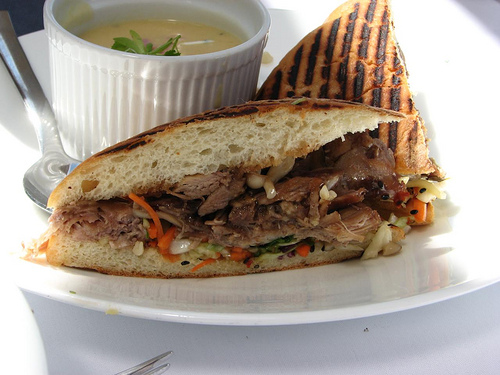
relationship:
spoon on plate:
[0, 9, 82, 211] [0, 27, 500, 327]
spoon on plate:
[0, 9, 82, 211] [3, 1, 483, 327]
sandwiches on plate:
[21, 1, 445, 280] [3, 1, 483, 327]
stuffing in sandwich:
[53, 124, 392, 236] [19, 96, 447, 280]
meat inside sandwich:
[52, 137, 399, 247] [30, 93, 412, 278]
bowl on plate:
[37, 0, 272, 162] [3, 1, 483, 327]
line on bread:
[316, 14, 341, 97] [253, 0, 434, 177]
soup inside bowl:
[89, 12, 219, 46] [37, 0, 272, 162]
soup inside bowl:
[89, 12, 219, 46] [44, 13, 260, 148]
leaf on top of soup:
[106, 22, 180, 55] [78, 15, 229, 53]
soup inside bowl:
[89, 12, 219, 46] [36, 1, 258, 142]